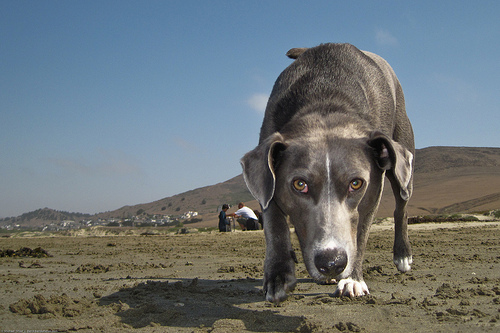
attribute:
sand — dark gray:
[2, 233, 499, 331]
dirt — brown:
[0, 230, 500, 330]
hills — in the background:
[423, 144, 491, 224]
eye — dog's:
[294, 169, 314, 201]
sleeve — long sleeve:
[232, 207, 244, 216]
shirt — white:
[235, 205, 256, 220]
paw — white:
[331, 275, 371, 300]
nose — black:
[312, 249, 348, 273]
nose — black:
[309, 235, 363, 275]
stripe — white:
[320, 150, 334, 247]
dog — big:
[231, 35, 428, 310]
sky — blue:
[34, 19, 224, 138]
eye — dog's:
[333, 176, 359, 206]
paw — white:
[326, 273, 380, 308]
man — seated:
[224, 198, 263, 231]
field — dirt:
[1, 227, 499, 332]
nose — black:
[304, 243, 356, 278]